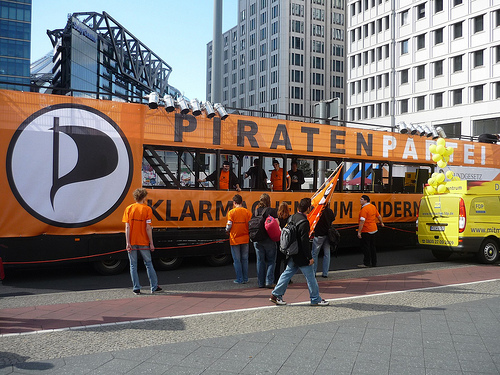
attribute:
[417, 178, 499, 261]
bus — yellow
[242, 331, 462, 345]
walkway — paved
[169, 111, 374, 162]
letters — black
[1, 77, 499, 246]
sign — yellow, black, orange, long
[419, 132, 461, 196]
balloons — yellow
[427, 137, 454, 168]
balloons — yellow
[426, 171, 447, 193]
balloons — yellow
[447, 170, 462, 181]
balloons — yellow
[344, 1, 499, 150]
office buildings — tall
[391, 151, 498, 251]
vehicle — yellow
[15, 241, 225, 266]
rope — orange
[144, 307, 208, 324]
line — white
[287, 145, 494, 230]
van — yellow 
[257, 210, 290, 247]
bag — red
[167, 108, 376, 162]
word — black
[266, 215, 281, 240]
bag — pink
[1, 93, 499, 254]
bus — big